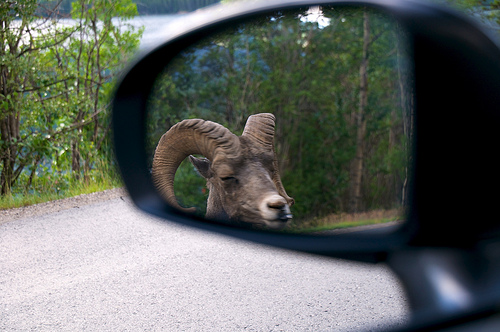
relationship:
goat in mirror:
[148, 109, 298, 245] [110, 0, 496, 327]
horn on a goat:
[156, 118, 243, 210] [148, 109, 298, 245]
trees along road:
[0, 0, 148, 210] [0, 185, 413, 329]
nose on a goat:
[262, 194, 288, 215] [148, 109, 298, 245]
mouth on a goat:
[250, 211, 299, 232] [148, 109, 298, 245]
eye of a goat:
[215, 167, 237, 190] [148, 109, 298, 245]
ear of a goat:
[151, 111, 294, 231] [148, 109, 298, 245]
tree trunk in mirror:
[352, 8, 367, 221] [110, 0, 496, 327]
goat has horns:
[148, 109, 298, 245] [146, 100, 322, 179]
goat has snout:
[148, 109, 298, 245] [234, 174, 311, 232]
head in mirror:
[138, 94, 335, 238] [93, 11, 483, 260]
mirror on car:
[88, 22, 469, 276] [91, 15, 479, 254]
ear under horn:
[186, 147, 214, 182] [155, 97, 255, 164]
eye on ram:
[215, 172, 237, 188] [162, 88, 332, 238]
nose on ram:
[262, 194, 288, 215] [154, 93, 354, 235]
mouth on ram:
[250, 191, 320, 232] [154, 93, 354, 235]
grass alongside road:
[23, 161, 104, 223] [0, 182, 412, 331]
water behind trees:
[30, 9, 97, 72] [25, 29, 90, 153]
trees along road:
[20, 55, 119, 231] [6, 167, 117, 290]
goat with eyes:
[148, 95, 346, 245] [210, 149, 304, 192]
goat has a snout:
[148, 109, 298, 245] [255, 189, 286, 215]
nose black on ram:
[262, 194, 300, 215] [172, 103, 307, 212]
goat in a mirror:
[148, 109, 298, 245] [162, 46, 414, 228]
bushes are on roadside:
[11, 16, 96, 169] [0, 177, 127, 227]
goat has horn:
[148, 109, 298, 245] [148, 118, 242, 216]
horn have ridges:
[148, 118, 242, 216] [183, 114, 220, 139]